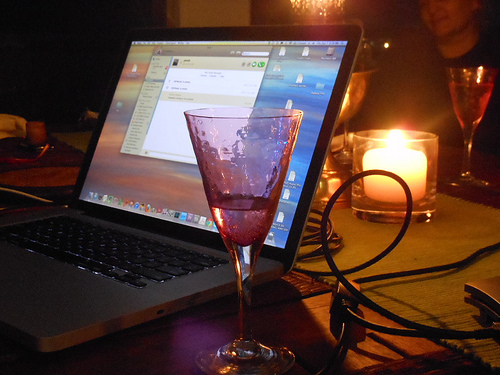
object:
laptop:
[1, 24, 365, 352]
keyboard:
[1, 215, 231, 288]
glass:
[184, 106, 304, 374]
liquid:
[209, 195, 275, 247]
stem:
[227, 247, 257, 344]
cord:
[292, 169, 500, 340]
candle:
[362, 147, 427, 204]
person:
[416, 0, 500, 157]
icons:
[186, 212, 193, 222]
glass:
[350, 129, 438, 224]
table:
[0, 132, 500, 375]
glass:
[443, 66, 498, 190]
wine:
[450, 80, 494, 130]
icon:
[101, 194, 109, 203]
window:
[120, 47, 273, 167]